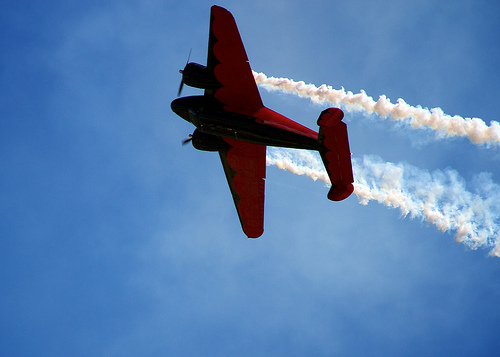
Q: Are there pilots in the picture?
A: No, there are no pilots.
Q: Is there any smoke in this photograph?
A: Yes, there is smoke.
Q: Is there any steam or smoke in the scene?
A: Yes, there is smoke.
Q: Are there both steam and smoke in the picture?
A: No, there is smoke but no steam.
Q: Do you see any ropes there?
A: No, there are no ropes.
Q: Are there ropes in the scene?
A: No, there are no ropes.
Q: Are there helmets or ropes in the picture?
A: No, there are no ropes or helmets.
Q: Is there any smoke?
A: Yes, there is smoke.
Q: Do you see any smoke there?
A: Yes, there is smoke.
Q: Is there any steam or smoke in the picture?
A: Yes, there is smoke.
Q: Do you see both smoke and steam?
A: No, there is smoke but no steam.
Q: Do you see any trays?
A: No, there are no trays.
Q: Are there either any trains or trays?
A: No, there are no trays or trains.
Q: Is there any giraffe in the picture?
A: No, there are no giraffes.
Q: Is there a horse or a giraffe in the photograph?
A: No, there are no giraffes or horses.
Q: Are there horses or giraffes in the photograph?
A: No, there are no giraffes or horses.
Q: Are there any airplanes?
A: Yes, there is an airplane.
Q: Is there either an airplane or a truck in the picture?
A: Yes, there is an airplane.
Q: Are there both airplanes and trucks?
A: No, there is an airplane but no trucks.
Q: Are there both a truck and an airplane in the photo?
A: No, there is an airplane but no trucks.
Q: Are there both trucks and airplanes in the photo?
A: No, there is an airplane but no trucks.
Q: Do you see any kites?
A: No, there are no kites.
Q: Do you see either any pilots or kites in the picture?
A: No, there are no kites or pilots.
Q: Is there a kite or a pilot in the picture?
A: No, there are no kites or pilots.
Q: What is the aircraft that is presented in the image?
A: The aircraft is an airplane.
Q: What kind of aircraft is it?
A: The aircraft is an airplane.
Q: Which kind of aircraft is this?
A: This is an airplane.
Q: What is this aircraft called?
A: This is an airplane.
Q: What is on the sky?
A: The airplane is on the sky.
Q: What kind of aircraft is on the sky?
A: The aircraft is an airplane.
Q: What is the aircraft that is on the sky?
A: The aircraft is an airplane.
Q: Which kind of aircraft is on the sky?
A: The aircraft is an airplane.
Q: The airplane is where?
A: The airplane is on the sky.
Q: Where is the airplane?
A: The airplane is on the sky.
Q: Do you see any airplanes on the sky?
A: Yes, there is an airplane on the sky.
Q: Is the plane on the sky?
A: Yes, the plane is on the sky.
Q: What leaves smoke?
A: The airplane leaves smoke.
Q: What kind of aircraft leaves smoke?
A: The aircraft is an airplane.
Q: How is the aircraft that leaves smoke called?
A: The aircraft is an airplane.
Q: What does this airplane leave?
A: The airplane leaves smoke.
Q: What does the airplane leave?
A: The airplane leaves smoke.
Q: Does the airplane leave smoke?
A: Yes, the airplane leaves smoke.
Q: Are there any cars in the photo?
A: No, there are no cars.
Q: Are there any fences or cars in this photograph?
A: No, there are no cars or fences.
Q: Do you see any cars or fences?
A: No, there are no cars or fences.